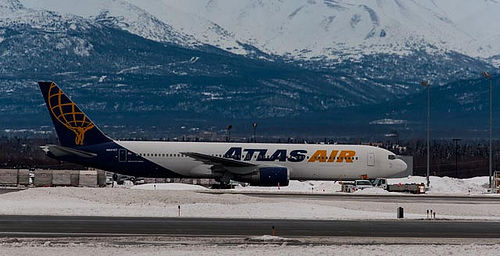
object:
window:
[386, 154, 398, 161]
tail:
[37, 82, 112, 148]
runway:
[0, 213, 500, 239]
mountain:
[234, 73, 500, 136]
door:
[366, 152, 376, 167]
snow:
[439, 205, 499, 216]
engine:
[208, 164, 291, 187]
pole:
[487, 77, 494, 188]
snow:
[433, 12, 494, 37]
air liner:
[32, 79, 409, 188]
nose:
[395, 157, 409, 175]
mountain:
[1, 7, 312, 69]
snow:
[428, 177, 489, 195]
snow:
[176, 193, 308, 216]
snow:
[6, 187, 173, 213]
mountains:
[229, 91, 319, 114]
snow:
[264, 0, 323, 53]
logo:
[47, 81, 94, 146]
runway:
[0, 187, 499, 206]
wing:
[177, 151, 291, 187]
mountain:
[120, 38, 346, 126]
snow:
[0, 0, 92, 33]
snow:
[305, 38, 377, 59]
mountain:
[286, 25, 497, 82]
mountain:
[485, 53, 500, 73]